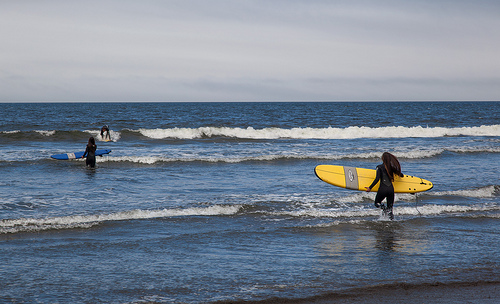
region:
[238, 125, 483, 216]
This is a surfer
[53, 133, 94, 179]
The surfboard is blue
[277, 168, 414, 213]
The surfboard is yellow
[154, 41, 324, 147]
The sky is cloudy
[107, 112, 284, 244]
This is the beautiful ocean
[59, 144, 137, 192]
This is a wetsuit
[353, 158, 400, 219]
The board is yellow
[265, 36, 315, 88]
The sky is grey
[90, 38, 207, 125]
The sky is empty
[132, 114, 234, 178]
The waves are white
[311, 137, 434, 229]
A woman holding a surfboard.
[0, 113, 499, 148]
a white wave in the ocean.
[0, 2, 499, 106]
A hazy gray sky.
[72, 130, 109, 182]
a person standing in the odean.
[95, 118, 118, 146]
a couple riding a wave together.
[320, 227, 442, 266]
A surf boarder's reflection.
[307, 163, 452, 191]
a long yellow surfboard.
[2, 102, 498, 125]
A calm blue ocean.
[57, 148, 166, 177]
White foam from a wave.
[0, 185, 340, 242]
A wave in the ocean.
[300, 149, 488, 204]
the surfboard is yellow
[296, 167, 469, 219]
the surfboard is yellow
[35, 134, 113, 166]
the surfboard is blue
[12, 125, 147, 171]
the surfboard is blue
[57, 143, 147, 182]
the surfboard is blue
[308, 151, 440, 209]
a surfer carrying a yellow surf board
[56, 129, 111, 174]
a surfer carrying a blue surf board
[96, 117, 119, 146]
a surfer on a yellow surf board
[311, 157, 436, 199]
a yellow surf board with a grey stripe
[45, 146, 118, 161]
a blue surfer with a grey stripe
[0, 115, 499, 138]
a wave nearing the beach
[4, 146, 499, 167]
a wave nearing the beach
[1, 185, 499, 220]
a wave nearing the beach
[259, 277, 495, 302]
sand on a beach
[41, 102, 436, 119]
the ocean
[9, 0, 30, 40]
white clouds in blue sky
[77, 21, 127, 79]
white clouds in blue sky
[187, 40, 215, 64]
white clouds in blue sky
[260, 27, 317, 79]
white clouds in blue sky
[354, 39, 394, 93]
white clouds in blue sky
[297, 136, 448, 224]
surfer with yellow board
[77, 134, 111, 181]
surfer with blue board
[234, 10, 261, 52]
white clouds in blue sky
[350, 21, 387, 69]
white clouds in blue sky